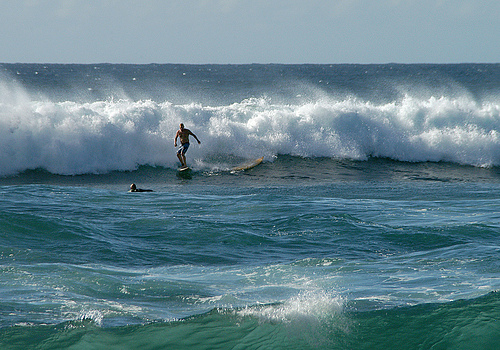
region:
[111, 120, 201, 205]
Two people are seen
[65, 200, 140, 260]
Water is blue color.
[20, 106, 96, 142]
waves are white color.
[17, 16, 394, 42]
sky is blue color.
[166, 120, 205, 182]
one man is surfing.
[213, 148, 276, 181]
one surfing board is floating.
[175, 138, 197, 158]
man is in blue shorts.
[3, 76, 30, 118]
water is splashing.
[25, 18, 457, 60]
sky is clear with no clouds.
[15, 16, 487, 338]
Day time picture.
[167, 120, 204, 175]
Man surfing on ocean water.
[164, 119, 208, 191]
Man on a surfboard behind a white wave.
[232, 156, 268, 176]
Surfboard in the water.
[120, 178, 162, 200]
Person in the water of the surfboard.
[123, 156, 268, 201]
Man and surfboard in the water.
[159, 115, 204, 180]
Man surfing on water between a man and surfboard.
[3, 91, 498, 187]
Large white wave behind the surfer.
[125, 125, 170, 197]
Man in the water in front a huge wave.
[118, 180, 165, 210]
Man swimming in the ocean.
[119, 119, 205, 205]
Men at the beach on the water.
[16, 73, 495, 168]
A large wave of water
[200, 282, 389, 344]
A small wave of water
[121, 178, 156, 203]
A person swimming in the water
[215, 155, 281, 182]
A surf board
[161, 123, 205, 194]
A person surfing in the water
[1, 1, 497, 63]
The blue sky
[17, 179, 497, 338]
deep water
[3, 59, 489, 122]
Mist created by waves of water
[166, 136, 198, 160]
Blue shorts worn by a man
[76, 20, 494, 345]
A group of people surfing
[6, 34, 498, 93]
The horizon line is clear.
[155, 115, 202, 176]
The man is surfing.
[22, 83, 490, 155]
The wave is breaking.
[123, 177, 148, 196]
A man is in the water.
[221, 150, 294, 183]
The surfboarding is in the water.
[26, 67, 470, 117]
Mist raises off the waves.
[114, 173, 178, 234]
The man is floating.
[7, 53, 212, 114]
Light shimmers off the water.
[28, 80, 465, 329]
The water is blue.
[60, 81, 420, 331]
The water is rough.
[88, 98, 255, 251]
two surfers in the water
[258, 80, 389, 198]
the waves are crashing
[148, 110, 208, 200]
he is on his board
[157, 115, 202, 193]
he is surfing in the water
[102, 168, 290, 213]
the surfer lost their board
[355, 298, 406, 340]
the water looks green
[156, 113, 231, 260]
the guy has no shirt on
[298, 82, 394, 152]
the waves are crashing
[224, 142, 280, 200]
a surfboard in the water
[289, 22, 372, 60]
the sky looks grey